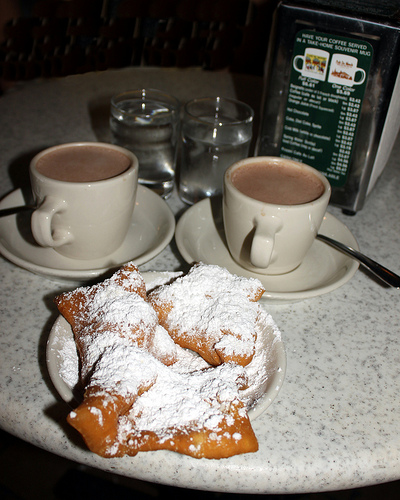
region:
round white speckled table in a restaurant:
[1, 64, 394, 491]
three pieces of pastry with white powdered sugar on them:
[41, 258, 282, 459]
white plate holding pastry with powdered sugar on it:
[45, 272, 285, 459]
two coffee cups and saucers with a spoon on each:
[0, 140, 361, 301]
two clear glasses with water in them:
[109, 87, 255, 205]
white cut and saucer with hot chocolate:
[176, 156, 358, 298]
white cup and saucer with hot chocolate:
[0, 142, 174, 283]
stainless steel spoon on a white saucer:
[311, 231, 397, 292]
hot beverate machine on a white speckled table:
[244, 1, 397, 214]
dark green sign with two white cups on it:
[253, 5, 397, 209]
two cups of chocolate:
[26, 147, 326, 275]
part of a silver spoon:
[320, 233, 397, 285]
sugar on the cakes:
[91, 282, 248, 421]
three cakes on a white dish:
[36, 267, 290, 455]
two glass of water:
[109, 85, 251, 155]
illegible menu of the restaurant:
[279, 33, 369, 162]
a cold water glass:
[188, 99, 249, 151]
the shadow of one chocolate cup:
[8, 146, 34, 242]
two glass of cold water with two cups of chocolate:
[27, 89, 326, 275]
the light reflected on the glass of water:
[211, 97, 248, 144]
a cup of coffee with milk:
[226, 157, 330, 276]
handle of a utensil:
[316, 229, 399, 289]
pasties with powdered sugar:
[51, 264, 265, 457]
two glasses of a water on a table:
[112, 89, 254, 207]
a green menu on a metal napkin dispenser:
[278, 19, 373, 195]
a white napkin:
[364, 63, 398, 195]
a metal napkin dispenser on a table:
[255, 4, 399, 214]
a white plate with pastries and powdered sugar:
[44, 273, 284, 420]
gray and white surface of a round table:
[3, 65, 396, 490]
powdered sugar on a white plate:
[48, 320, 79, 391]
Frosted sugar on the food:
[54, 267, 266, 458]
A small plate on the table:
[44, 284, 282, 426]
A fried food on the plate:
[51, 262, 264, 459]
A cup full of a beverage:
[223, 157, 331, 274]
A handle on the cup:
[250, 215, 280, 267]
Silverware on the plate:
[316, 232, 398, 288]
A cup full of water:
[176, 94, 253, 204]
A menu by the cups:
[260, 5, 397, 214]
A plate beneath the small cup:
[178, 191, 358, 293]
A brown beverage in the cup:
[230, 162, 324, 206]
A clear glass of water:
[172, 91, 249, 203]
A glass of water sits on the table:
[101, 76, 176, 196]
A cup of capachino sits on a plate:
[18, 135, 143, 261]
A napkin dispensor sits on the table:
[244, 1, 398, 215]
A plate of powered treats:
[36, 257, 282, 462]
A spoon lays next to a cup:
[318, 225, 399, 301]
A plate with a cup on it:
[174, 157, 359, 298]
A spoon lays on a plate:
[0, 201, 25, 221]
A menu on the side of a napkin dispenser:
[275, 25, 369, 190]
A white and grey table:
[2, 71, 398, 493]